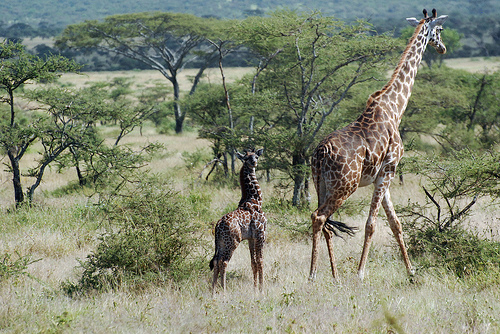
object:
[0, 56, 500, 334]
grass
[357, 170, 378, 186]
stomach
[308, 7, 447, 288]
giraffe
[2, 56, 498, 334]
ground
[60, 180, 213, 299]
bush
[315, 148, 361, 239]
tail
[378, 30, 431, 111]
neck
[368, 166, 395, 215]
thigh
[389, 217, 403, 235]
knee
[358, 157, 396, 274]
leg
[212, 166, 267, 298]
baby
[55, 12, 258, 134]
tree